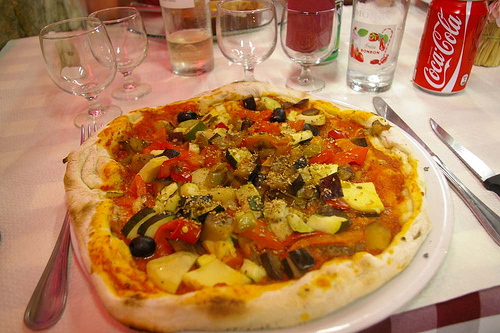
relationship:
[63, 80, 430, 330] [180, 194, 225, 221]
pizza has a vegetable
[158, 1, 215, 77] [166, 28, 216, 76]
glass has tea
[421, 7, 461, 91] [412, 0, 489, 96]
coca cola on can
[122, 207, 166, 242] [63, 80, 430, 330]
zucchini on pizza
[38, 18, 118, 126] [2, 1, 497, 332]
glass on table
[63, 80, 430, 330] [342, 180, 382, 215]
pizza has pineapple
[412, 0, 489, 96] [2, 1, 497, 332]
can on table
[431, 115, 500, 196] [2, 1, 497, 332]
knife on table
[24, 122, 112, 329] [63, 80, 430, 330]
fork by pizza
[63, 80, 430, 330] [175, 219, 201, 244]
pizza has a pepper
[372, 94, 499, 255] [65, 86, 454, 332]
knife next to plate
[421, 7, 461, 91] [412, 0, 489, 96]
coca cola in can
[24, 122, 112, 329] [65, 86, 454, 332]
fork by plate